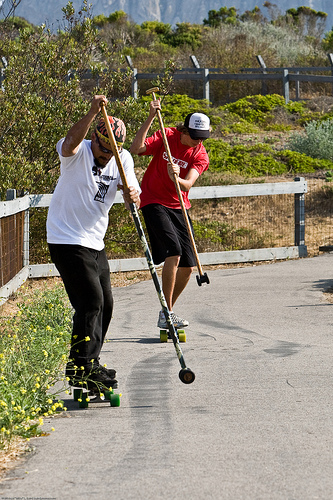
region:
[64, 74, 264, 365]
two people are on skating boards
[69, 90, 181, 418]
man is holding a skating stick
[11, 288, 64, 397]
plants are grown beside the road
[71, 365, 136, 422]
wheels are green in color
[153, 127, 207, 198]
the t shirt is red in color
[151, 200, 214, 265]
the short is black in color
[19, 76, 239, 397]
Two men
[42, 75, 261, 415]
The men are skateboarding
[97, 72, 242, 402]
They are holding poles with wheels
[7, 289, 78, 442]
Green weeds with yellow flowers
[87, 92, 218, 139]
The men are wearing hats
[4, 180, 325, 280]
A fence behind the men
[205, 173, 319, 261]
The fence posts are made of wood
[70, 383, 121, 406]
the wheels are green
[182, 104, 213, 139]
the hat is black and white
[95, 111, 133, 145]
the helmet is black and red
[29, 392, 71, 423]
the flowers are yellow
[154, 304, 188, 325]
the shoes are white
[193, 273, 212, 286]
the wheels are black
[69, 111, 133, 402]
the man has glasses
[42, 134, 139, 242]
white shirt on man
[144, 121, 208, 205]
red shirt on man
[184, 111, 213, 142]
black and white hat on man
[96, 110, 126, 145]
hat on the man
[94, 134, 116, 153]
glasses on man's face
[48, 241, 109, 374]
black pants of skater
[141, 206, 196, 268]
black shorts of skater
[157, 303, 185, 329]
white shoes of skater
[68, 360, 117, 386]
black shoes of player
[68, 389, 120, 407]
green wheels of board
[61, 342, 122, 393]
Man wearing black shoes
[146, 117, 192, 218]
man wearing a red shirt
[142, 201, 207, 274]
man wearing black shorts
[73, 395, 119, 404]
green wheels on a skateboard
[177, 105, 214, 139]
man wearing a black hat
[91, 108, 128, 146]
man wearing a flaming skull cap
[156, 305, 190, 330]
man wearing white shoes